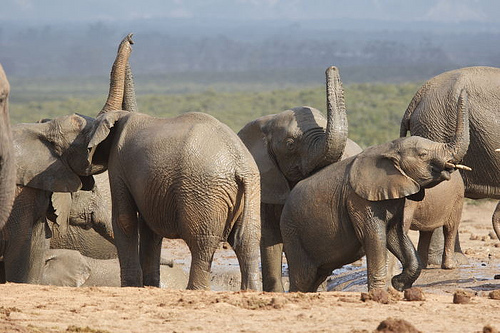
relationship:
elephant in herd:
[393, 65, 498, 246] [0, 31, 498, 304]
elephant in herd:
[277, 88, 471, 293] [0, 31, 498, 304]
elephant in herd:
[231, 72, 359, 289] [0, 31, 498, 304]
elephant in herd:
[77, 82, 269, 295] [0, 31, 498, 304]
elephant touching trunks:
[77, 82, 269, 295] [94, 30, 151, 117]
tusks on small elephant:
[443, 162, 472, 176] [283, 86, 475, 302]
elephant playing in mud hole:
[277, 88, 471, 293] [0, 178, 497, 329]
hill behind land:
[4, 12, 499, 77] [0, 90, 498, 330]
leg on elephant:
[184, 228, 217, 296] [277, 88, 471, 293]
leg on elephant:
[227, 207, 270, 299] [64, 91, 264, 311]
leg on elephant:
[111, 179, 143, 285] [80, 109, 261, 293]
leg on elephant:
[351, 210, 403, 318] [277, 88, 471, 293]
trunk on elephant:
[445, 87, 469, 164] [277, 88, 471, 293]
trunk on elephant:
[303, 65, 349, 176] [231, 72, 359, 289]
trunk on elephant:
[95, 33, 133, 115] [3, 30, 134, 283]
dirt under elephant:
[0, 197, 498, 330] [277, 88, 471, 293]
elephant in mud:
[277, 88, 471, 293] [0, 195, 499, 330]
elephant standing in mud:
[277, 88, 471, 293] [175, 245, 497, 290]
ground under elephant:
[2, 287, 499, 332] [59, 104, 273, 293]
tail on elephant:
[230, 159, 249, 252] [85, 107, 271, 307]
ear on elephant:
[350, 152, 430, 217] [277, 88, 471, 293]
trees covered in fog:
[2, 18, 498, 83] [1, 0, 498, 78]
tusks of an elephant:
[443, 162, 472, 176] [277, 88, 471, 293]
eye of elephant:
[417, 148, 428, 158] [277, 88, 471, 293]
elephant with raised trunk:
[235, 114, 371, 296] [310, 59, 350, 174]